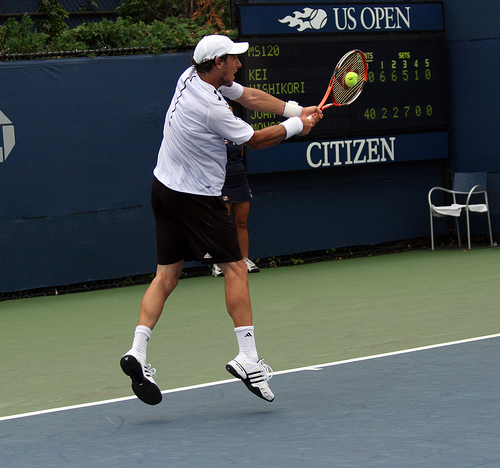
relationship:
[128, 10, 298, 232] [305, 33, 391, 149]
player holding racket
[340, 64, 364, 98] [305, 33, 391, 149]
ball on racket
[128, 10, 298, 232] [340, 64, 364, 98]
player hits ball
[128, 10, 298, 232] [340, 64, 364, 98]
player hit ball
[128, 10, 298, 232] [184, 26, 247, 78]
player wearing cap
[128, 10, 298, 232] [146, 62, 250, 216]
player wearing shirt